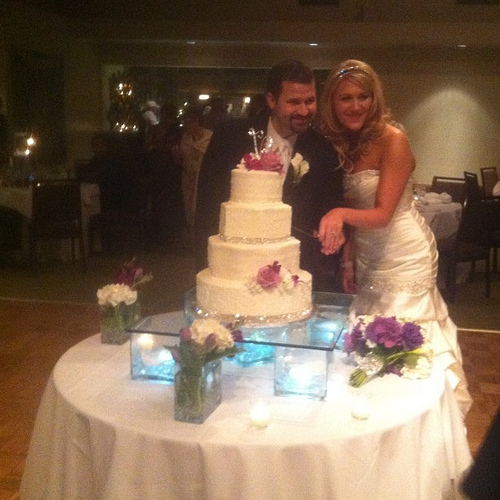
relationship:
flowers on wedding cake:
[252, 243, 317, 300] [194, 150, 315, 329]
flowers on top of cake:
[242, 148, 283, 171] [178, 161, 319, 321]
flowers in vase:
[320, 295, 438, 380] [169, 354, 223, 424]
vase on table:
[169, 354, 223, 424] [12, 310, 474, 499]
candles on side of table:
[325, 378, 412, 490] [274, 360, 390, 498]